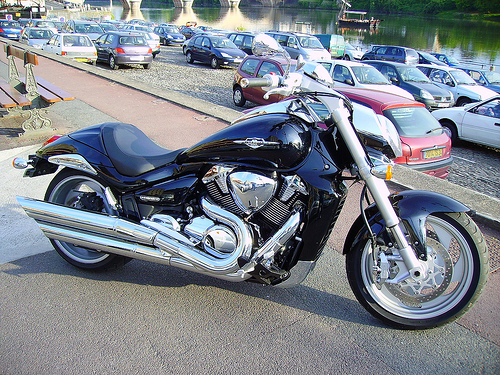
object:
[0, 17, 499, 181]
cars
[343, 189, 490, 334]
tire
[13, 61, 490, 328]
bike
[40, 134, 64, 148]
signal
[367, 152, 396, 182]
signal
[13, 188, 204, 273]
exhaust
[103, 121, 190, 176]
seat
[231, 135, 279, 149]
emblem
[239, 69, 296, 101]
handlebar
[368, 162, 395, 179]
headlight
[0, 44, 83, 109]
bench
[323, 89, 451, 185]
car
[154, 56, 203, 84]
gravel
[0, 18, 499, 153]
lot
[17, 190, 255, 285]
pipes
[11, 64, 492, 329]
motorcycle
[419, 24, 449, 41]
water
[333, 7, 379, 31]
boat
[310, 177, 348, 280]
shade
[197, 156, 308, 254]
metal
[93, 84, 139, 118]
road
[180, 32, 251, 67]
car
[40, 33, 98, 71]
car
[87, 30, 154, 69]
car